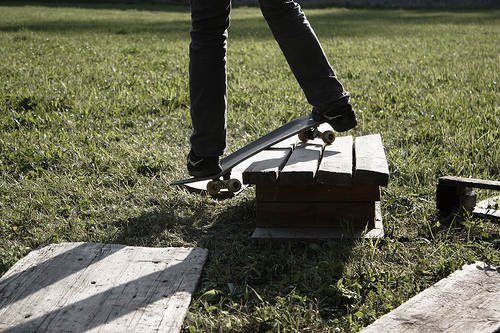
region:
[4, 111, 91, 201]
A green grass field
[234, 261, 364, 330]
A green grass field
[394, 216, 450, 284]
A green grass field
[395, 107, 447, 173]
A green grass field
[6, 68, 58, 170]
A green grass field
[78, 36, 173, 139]
A green grass field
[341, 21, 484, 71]
A green grass field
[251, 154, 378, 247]
A wooden pile of timber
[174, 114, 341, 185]
A black sketing board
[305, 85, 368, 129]
A black sketing shoe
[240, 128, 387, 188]
planks of wood stacked up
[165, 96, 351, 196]
skateboard on top of stacked wood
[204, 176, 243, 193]
wheels on bottom of skateboard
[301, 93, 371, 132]
black sneaker on foot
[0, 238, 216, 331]
plywood laying on ground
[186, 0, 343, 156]
black denim on person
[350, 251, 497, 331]
plank of old wood on ground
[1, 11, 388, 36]
shadow being cast on ground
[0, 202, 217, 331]
shadow of the person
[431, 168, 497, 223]
old wood stacked up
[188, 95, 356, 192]
balck skateboard with yellow wheels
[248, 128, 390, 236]
wooden slatted base for skateboard jump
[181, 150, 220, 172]
black puma sneaker with white cat logo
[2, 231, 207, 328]
gray wooden plank on yard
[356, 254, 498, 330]
gray wooden plank on yard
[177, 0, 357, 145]
boy wearing dark jeans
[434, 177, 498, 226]
a small home made performance step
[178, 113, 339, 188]
black skateboard tips toward ground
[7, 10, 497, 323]
green grassy field for boy to play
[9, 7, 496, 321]
outdoor sunny daytime skateboarding scene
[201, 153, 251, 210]
the wheels on a skateboard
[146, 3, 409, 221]
a person on a skateboard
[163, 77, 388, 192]
a person wearing shoes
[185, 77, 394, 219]
a skateboard on wood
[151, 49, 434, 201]
shoes on a skateboard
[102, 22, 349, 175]
a person wearing jeans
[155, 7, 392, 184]
a person wearing black jeans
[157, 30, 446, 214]
a person wearing black shoes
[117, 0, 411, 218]
a grassy area near a skateboard